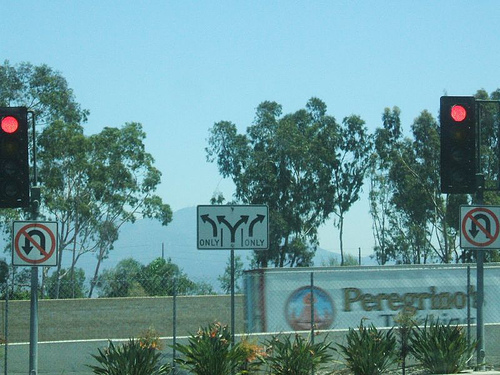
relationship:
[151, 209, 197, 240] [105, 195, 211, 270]
mountains in distance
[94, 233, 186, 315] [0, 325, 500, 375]
wall behind road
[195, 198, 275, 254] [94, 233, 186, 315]
sign on wall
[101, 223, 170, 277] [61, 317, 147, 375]
plant near road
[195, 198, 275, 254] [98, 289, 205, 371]
sign on side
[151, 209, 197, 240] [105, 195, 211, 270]
mountains at distance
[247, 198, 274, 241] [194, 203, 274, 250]
arrow on sign